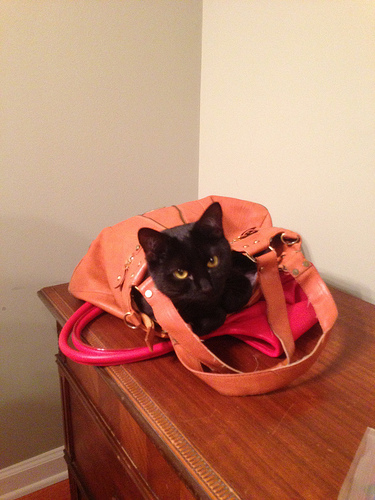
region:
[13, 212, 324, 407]
this is in a bedroom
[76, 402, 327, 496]
this is a desk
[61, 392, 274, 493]
the desk drawers are dark brown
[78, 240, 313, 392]
this is a cat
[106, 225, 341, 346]
the cat is black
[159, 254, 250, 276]
the cat's eyes are yellow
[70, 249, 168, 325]
this is a purse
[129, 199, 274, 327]
black cat inside of orange purse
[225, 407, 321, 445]
scratches on top of dresser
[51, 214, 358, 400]
orange purse ontop of pink purse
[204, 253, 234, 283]
golden eye on cat's left side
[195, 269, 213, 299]
black nose on cat's face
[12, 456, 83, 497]
white baseboard at bottom of photo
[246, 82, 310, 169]
cream colored area on wall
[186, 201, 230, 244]
black ear on right side of photo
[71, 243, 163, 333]
this purse is orange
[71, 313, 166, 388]
this purse is pink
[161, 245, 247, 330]
this is a black cat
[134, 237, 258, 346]
the cat is looking at the camera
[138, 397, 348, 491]
the dresser is made of wood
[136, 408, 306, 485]
the dresser is brown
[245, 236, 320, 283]
there is metal on the handles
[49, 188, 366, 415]
the cat is in a purse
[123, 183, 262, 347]
the cat is black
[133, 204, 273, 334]
this is a black cat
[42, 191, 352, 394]
a salmon leather purse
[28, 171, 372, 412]
there are two purses on top of each other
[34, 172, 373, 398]
two purses on top of the cabinet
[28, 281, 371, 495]
this is a wooden cabinet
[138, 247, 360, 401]
this is a shoulder strap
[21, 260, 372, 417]
the bottom purse is hot pink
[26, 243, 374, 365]
the purse on the bottom is a brighter pink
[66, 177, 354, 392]
black cat inside orange purse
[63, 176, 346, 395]
black cat inside orange purse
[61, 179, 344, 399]
black cat inside orange purse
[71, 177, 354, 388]
black cat inside orange purse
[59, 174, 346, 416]
black cat inside orange purse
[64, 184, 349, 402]
black cat inside orange purse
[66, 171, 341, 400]
black cat inside orange purse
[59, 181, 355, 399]
black cat inside orange purse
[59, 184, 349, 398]
black cat inside orange purse